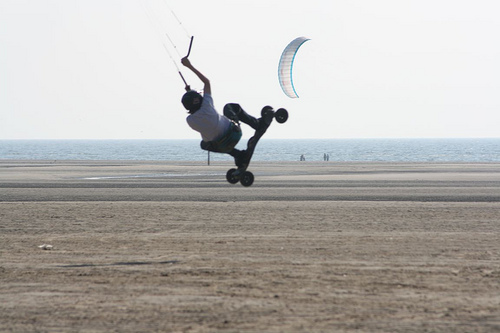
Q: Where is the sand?
A: Ground.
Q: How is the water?
A: Blue.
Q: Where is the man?
A: In air.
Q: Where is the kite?
A: In the air.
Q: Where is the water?
A: In the ocean.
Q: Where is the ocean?
A: Past the beach.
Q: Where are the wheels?
A: On the board.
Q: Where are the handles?
A: In the hands.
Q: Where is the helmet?
A: On the man.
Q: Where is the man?
A: In the air.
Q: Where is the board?
A: In the air.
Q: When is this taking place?
A: Daytime.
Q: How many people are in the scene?
A: One.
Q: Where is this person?
A: In the air.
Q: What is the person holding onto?
A: Rope.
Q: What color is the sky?
A: White.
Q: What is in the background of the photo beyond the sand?
A: Water.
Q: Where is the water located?
A: Beach.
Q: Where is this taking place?
A: At the beach.